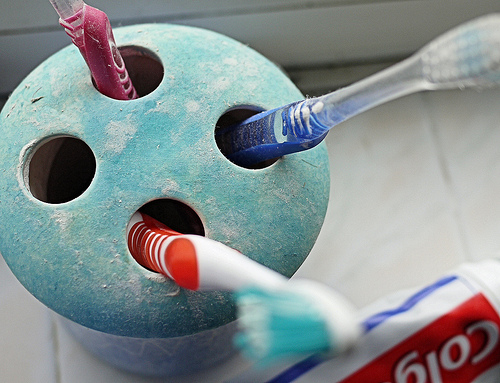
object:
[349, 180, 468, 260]
white countertop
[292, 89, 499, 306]
countertop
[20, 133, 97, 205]
holes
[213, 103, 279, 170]
holes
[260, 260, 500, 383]
colgate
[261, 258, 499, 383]
tube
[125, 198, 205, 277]
slot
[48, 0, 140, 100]
toothbrush handle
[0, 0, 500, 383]
ground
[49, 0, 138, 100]
toothbrush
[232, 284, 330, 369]
bristles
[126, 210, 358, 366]
toothbrush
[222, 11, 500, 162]
toothbrush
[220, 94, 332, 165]
handle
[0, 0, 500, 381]
counter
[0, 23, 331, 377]
holder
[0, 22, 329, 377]
stand